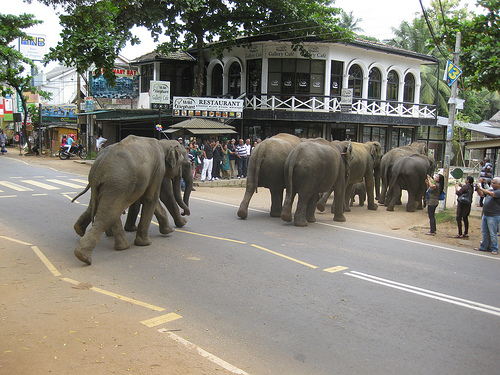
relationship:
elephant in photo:
[75, 135, 190, 266] [1, 2, 499, 374]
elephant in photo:
[280, 141, 353, 228] [1, 2, 499, 374]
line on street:
[251, 242, 317, 271] [1, 155, 499, 374]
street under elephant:
[1, 155, 499, 374] [75, 135, 190, 266]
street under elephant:
[1, 155, 499, 374] [280, 141, 353, 228]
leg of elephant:
[134, 175, 164, 247] [75, 135, 190, 266]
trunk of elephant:
[172, 177, 189, 217] [75, 135, 190, 266]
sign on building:
[172, 97, 245, 112] [173, 24, 440, 157]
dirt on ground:
[317, 206, 499, 254] [316, 207, 499, 257]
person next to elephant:
[424, 173, 446, 235] [280, 141, 353, 228]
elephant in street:
[75, 135, 190, 266] [1, 155, 499, 374]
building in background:
[173, 24, 440, 157] [1, 0, 499, 189]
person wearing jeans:
[475, 179, 499, 256] [480, 215, 500, 251]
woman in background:
[59, 133, 71, 156] [1, 0, 499, 189]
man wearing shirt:
[202, 140, 215, 181] [205, 143, 214, 157]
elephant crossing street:
[75, 135, 190, 266] [1, 155, 499, 374]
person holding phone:
[424, 173, 446, 235] [426, 171, 429, 176]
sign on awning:
[172, 97, 245, 112] [95, 115, 248, 118]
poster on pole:
[87, 65, 141, 105] [82, 65, 91, 161]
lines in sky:
[419, 0, 449, 60] [331, 0, 433, 43]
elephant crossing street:
[280, 141, 353, 228] [1, 155, 499, 374]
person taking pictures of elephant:
[424, 173, 446, 235] [75, 135, 190, 266]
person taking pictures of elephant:
[424, 173, 446, 235] [280, 141, 353, 228]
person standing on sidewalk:
[236, 140, 249, 181] [193, 178, 246, 189]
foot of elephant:
[73, 243, 94, 266] [75, 135, 190, 266]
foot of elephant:
[136, 228, 150, 246] [75, 135, 190, 266]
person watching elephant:
[424, 173, 446, 235] [75, 135, 190, 266]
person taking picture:
[424, 173, 446, 235] [425, 170, 430, 176]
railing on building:
[217, 94, 438, 119] [173, 24, 440, 157]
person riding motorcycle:
[68, 134, 77, 154] [60, 143, 90, 161]